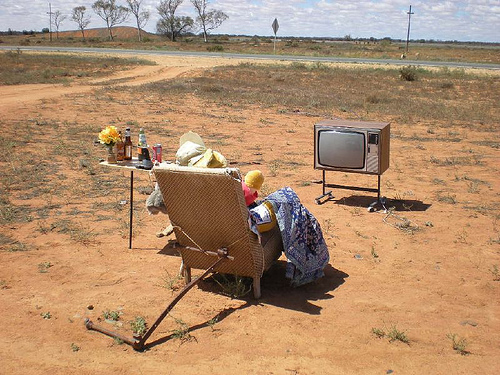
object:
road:
[0, 44, 499, 70]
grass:
[207, 66, 426, 105]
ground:
[334, 211, 499, 374]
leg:
[128, 170, 134, 249]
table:
[101, 156, 163, 172]